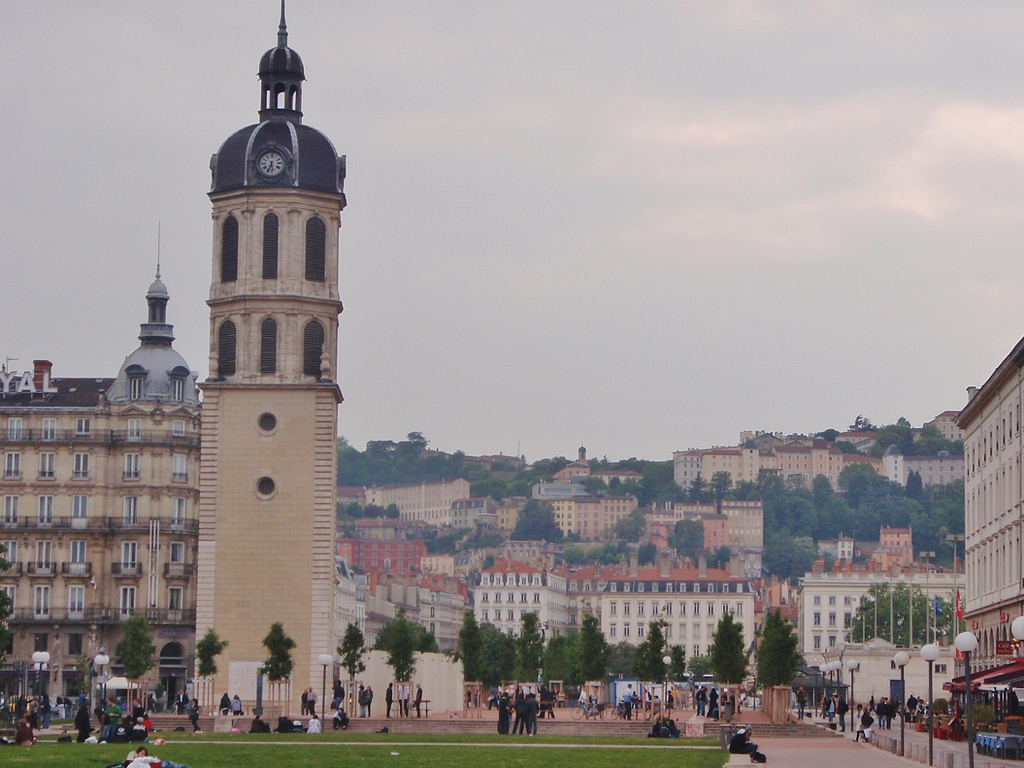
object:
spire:
[277, 1, 288, 46]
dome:
[258, 47, 304, 76]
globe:
[920, 644, 940, 660]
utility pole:
[927, 660, 933, 768]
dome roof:
[206, 123, 345, 196]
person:
[728, 728, 765, 764]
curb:
[725, 753, 753, 768]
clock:
[257, 152, 285, 178]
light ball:
[955, 632, 977, 652]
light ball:
[1011, 617, 1024, 644]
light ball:
[920, 644, 940, 661]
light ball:
[893, 651, 909, 666]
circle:
[254, 410, 279, 436]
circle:
[251, 474, 277, 501]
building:
[191, 0, 347, 718]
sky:
[0, 0, 1019, 467]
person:
[120, 742, 166, 768]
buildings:
[673, 434, 883, 499]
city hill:
[334, 411, 963, 719]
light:
[1008, 616, 1024, 767]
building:
[601, 592, 757, 677]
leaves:
[260, 621, 296, 681]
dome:
[103, 279, 198, 406]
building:
[952, 341, 1024, 681]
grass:
[0, 730, 727, 768]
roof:
[206, 122, 348, 206]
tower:
[193, 46, 345, 719]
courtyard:
[0, 713, 925, 768]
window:
[124, 544, 131, 569]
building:
[0, 360, 200, 714]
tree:
[336, 623, 367, 715]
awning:
[940, 662, 1024, 742]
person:
[498, 692, 514, 735]